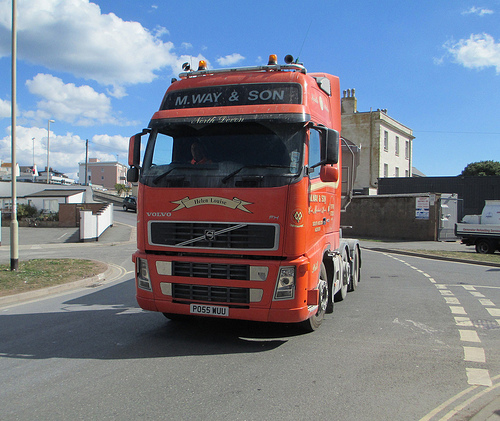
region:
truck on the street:
[120, 51, 397, 327]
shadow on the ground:
[48, 303, 117, 381]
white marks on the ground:
[433, 284, 485, 347]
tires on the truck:
[291, 255, 362, 327]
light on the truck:
[251, 258, 301, 316]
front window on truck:
[143, 102, 315, 194]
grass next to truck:
[40, 266, 72, 284]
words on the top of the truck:
[164, 74, 326, 114]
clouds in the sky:
[18, 23, 143, 150]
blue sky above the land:
[328, 21, 389, 53]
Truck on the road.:
[83, 35, 420, 340]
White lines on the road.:
[425, 257, 475, 352]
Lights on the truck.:
[134, 200, 361, 345]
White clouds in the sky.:
[60, 2, 260, 129]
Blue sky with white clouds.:
[123, 5, 421, 84]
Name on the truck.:
[159, 79, 368, 151]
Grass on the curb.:
[28, 215, 142, 286]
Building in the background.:
[333, 76, 446, 268]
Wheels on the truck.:
[282, 237, 380, 312]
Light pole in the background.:
[39, 119, 93, 210]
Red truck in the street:
[110, 56, 382, 368]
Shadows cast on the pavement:
[19, 273, 228, 381]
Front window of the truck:
[140, 102, 312, 195]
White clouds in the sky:
[29, 43, 113, 142]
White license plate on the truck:
[178, 294, 242, 324]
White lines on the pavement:
[401, 260, 497, 399]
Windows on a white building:
[373, 119, 419, 181]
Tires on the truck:
[294, 233, 370, 331]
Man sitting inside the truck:
[176, 126, 217, 183]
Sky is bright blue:
[353, 38, 418, 93]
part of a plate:
[188, 284, 236, 319]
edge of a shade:
[178, 322, 240, 364]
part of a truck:
[210, 240, 283, 329]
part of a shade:
[112, 315, 178, 374]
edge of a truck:
[278, 224, 310, 323]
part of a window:
[246, 132, 288, 167]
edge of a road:
[3, 274, 54, 301]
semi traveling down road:
[114, 2, 415, 373]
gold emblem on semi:
[155, 182, 266, 209]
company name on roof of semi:
[152, 90, 301, 110]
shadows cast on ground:
[0, 291, 282, 361]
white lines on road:
[358, 244, 499, 391]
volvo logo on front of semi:
[118, 205, 181, 232]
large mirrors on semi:
[322, 111, 345, 191]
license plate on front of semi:
[180, 297, 238, 317]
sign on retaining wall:
[410, 191, 432, 222]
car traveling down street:
[123, 196, 135, 213]